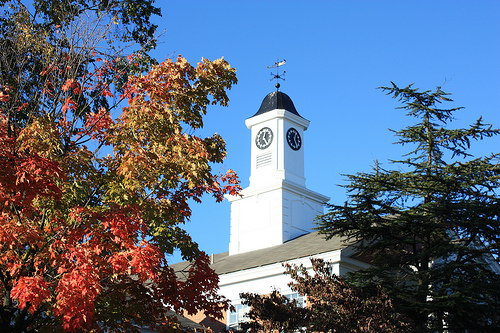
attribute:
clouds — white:
[302, 138, 369, 174]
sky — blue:
[0, 1, 499, 279]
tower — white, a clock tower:
[218, 52, 331, 260]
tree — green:
[325, 82, 495, 332]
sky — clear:
[15, 5, 498, 180]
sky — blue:
[332, 38, 412, 60]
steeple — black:
[243, 84, 309, 189]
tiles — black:
[190, 52, 498, 323]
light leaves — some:
[137, 98, 224, 206]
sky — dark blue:
[295, 15, 447, 84]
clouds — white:
[316, 123, 365, 169]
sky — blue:
[163, 10, 208, 48]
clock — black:
[254, 123, 274, 152]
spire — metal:
[253, 52, 332, 90]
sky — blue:
[297, 12, 410, 64]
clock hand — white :
[257, 127, 271, 145]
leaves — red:
[7, 233, 113, 331]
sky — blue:
[167, 8, 482, 68]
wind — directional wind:
[100, 3, 380, 145]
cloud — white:
[154, 48, 214, 83]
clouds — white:
[155, 12, 237, 77]